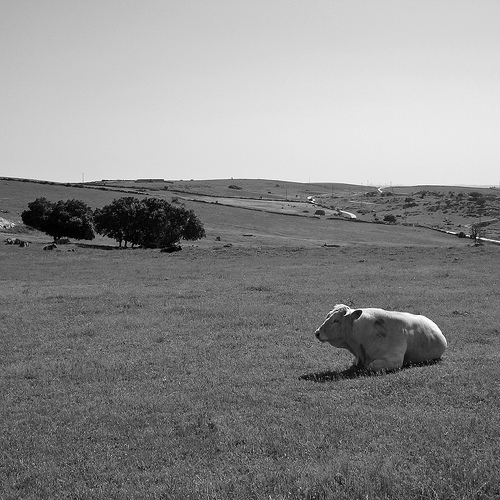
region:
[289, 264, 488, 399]
A cow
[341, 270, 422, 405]
A cow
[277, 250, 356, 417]
A cow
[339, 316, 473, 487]
A cow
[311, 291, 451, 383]
a white cow lying alone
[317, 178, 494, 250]
a road disappears on the horizon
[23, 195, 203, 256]
two trees offer shade in the pasture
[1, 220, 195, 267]
some cows of the herd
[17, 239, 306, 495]
a large grassy pature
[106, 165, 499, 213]
a ridge in the distance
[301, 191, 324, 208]
a building in the lowland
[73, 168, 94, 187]
barely visable power line pole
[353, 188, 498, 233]
brush growing across the road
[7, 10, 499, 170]
a clear sunny sky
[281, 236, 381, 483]
A cow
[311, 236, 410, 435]
A cow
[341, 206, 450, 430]
A cow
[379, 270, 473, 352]
A cow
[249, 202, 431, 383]
A cow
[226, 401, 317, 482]
The grass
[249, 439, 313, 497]
The grass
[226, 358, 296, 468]
The grass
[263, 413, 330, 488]
The grass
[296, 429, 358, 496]
The grass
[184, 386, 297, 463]
The grass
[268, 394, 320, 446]
The grass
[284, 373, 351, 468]
The grass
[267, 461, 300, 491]
The grass